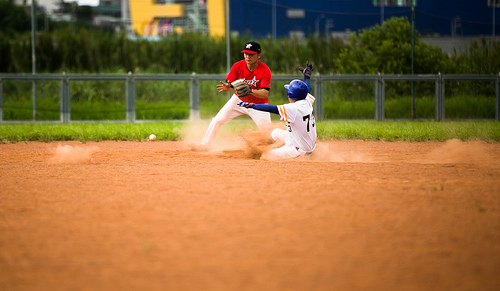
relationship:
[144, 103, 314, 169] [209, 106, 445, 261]
dust on field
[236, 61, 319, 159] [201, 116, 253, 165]
man to base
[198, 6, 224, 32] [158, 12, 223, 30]
part of building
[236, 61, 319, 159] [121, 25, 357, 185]
man playing baseball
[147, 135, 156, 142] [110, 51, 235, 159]
ball in mid air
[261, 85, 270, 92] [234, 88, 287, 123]
sleeve on arm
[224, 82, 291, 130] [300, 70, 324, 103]
sleeve on arm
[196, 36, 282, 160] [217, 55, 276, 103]
baseman wearing shirt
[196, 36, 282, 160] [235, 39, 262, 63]
baseman wearing cap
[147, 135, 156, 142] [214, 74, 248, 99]
ball on hand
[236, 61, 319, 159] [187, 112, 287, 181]
man into base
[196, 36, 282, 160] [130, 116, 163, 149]
baseman catch ball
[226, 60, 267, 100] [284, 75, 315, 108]
jersey wearing helmet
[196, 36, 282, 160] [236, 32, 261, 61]
baseman wearing hat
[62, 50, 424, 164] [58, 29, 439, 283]
wall along outfield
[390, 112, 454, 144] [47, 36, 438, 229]
grass in outfield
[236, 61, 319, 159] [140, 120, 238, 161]
man in dust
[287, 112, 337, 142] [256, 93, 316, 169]
numbers on jersey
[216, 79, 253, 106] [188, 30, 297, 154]
glove on baseman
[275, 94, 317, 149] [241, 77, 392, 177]
baseball jersey on man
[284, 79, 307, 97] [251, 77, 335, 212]
baseball helmet on man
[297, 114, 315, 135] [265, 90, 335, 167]
numbers on jersey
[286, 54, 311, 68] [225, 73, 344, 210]
glove on man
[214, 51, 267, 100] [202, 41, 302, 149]
jersey on man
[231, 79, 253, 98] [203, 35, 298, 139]
glove on man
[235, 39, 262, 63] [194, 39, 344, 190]
cap on man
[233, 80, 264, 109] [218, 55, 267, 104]
letters on jersey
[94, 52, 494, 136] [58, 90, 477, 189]
fence around field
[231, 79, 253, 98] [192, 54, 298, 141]
glove on man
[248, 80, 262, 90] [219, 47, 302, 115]
letters on shirt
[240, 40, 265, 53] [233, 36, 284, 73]
logo on hat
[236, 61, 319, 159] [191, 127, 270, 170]
man sliding base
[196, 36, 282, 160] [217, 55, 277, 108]
baseman in jersey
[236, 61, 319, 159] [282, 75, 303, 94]
man wearing helmet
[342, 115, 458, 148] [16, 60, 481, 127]
grass growing fence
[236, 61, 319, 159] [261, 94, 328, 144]
man wearing jersey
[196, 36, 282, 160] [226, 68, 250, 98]
baseman wearing glove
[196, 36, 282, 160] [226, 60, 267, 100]
baseman in jersey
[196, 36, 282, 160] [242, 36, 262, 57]
baseman with cap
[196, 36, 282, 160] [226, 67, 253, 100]
baseman holding glove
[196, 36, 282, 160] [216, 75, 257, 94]
baseman wearing glove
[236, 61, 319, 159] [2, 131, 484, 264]
man person field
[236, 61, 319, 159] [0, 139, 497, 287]
man sliding in dirt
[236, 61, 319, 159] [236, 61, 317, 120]
man has arm